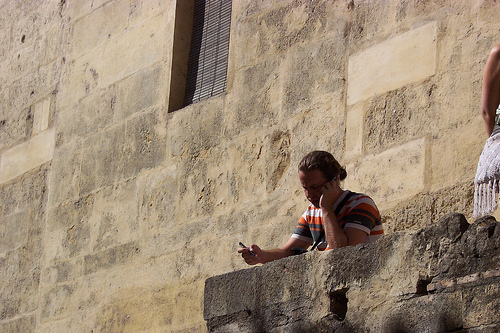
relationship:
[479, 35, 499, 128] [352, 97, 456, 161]
woman standing by wall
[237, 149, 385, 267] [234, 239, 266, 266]
man has man hand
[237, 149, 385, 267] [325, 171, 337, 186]
man on phone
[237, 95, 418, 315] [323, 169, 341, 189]
man holding cell phone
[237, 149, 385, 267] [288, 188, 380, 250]
man wearing a shirt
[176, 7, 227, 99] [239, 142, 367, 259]
window above man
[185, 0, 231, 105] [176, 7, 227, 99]
blinds in window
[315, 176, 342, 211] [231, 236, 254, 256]
hand holding phone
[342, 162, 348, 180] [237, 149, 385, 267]
ponytail on man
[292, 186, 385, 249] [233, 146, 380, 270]
shirt on a man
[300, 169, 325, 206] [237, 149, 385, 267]
face on man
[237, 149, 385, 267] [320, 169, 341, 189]
man talking on cell phone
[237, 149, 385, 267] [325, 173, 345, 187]
man holding cellphone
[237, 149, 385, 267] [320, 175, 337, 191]
man talking on cellphone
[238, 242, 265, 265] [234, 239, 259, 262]
hand holding pen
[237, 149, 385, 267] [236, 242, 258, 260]
man talking on phone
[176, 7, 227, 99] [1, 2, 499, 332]
window on building